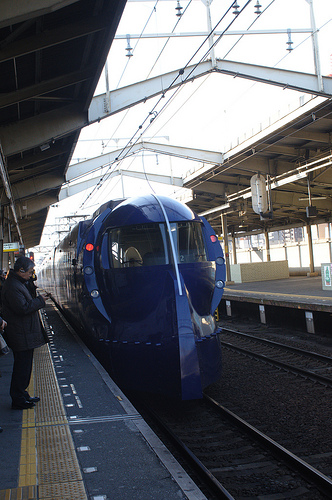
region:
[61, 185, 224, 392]
a blue speed train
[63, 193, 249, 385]
a blue passenger train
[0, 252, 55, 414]
a man waiting for his train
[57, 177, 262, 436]
a blue passenger train stopped at the station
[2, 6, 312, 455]
a train stop platform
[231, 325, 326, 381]
empty train tracks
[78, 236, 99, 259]
red light on the train signaling it is stopped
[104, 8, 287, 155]
wire system guiding the train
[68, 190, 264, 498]
a train stationary on the train tracks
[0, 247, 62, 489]
a man looking at his phone at the train stop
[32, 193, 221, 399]
the blue train on the track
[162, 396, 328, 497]
the track in front of the train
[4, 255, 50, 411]
the man standing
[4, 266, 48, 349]
the dark jacket on the man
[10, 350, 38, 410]
the man's legs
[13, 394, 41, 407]
the two feet on the man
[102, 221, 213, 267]
the window on the train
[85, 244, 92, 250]
the red light on the train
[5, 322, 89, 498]
the yellow markings on the ground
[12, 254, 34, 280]
the man's head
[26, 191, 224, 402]
The train is blue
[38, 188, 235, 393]
The train is at the station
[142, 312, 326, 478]
There are two rail road tracks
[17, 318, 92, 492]
Yellow line on the station platform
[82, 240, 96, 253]
Red round light on front of train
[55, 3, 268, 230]
The wires are black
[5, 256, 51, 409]
The man is standing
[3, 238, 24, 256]
White and yellow sign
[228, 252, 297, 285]
The wall is tan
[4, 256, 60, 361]
The man is wearing a black jacket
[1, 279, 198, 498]
train platform with people waiting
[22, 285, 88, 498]
yellow safty line for train platform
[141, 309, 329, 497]
train tracks center between platforms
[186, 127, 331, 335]
platform across the track of train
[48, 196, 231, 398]
front of big blue passenger train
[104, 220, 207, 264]
driver front window of train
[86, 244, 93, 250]
red light on big blue train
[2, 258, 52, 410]
man standing looking at cellphone on platform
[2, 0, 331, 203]
roof area of train station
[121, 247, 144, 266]
seat of train driver empty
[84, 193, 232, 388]
blue front of train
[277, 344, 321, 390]
metal train track on side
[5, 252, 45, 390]
man standing on sidewalk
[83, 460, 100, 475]
spot on the sidewalk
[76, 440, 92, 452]
square on the sidewalk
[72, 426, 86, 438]
square on the sidewalk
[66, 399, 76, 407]
square on the sidewalk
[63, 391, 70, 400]
square on the sidewalk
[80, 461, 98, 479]
square on the sidewalk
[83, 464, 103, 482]
square on the sidewalk